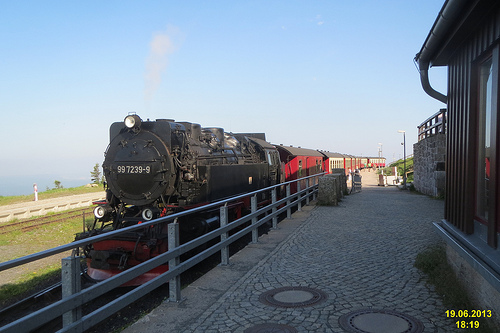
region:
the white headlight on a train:
[124, 115, 135, 127]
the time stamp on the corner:
[445, 309, 492, 329]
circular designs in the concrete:
[246, 283, 428, 332]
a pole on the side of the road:
[31, 184, 39, 199]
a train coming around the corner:
[78, 112, 385, 290]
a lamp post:
[397, 128, 405, 180]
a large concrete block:
[318, 174, 340, 207]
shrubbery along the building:
[413, 243, 498, 331]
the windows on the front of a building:
[468, 60, 498, 236]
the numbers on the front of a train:
[115, 163, 150, 175]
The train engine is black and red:
[86, 109, 285, 279]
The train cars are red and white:
[276, 142, 386, 202]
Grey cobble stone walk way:
[213, 177, 456, 330]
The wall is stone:
[408, 120, 444, 199]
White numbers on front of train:
[114, 160, 157, 177]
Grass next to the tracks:
[3, 178, 112, 300]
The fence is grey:
[8, 160, 320, 327]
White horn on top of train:
[120, 109, 143, 130]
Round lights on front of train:
[91, 199, 156, 226]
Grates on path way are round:
[248, 274, 420, 331]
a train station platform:
[124, 185, 468, 330]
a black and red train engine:
[77, 111, 283, 291]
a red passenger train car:
[275, 141, 325, 201]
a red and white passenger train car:
[321, 148, 344, 175]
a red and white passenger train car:
[344, 150, 352, 171]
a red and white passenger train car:
[360, 153, 367, 167]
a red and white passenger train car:
[369, 153, 386, 168]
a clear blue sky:
[4, 0, 451, 197]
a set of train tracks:
[0, 270, 174, 330]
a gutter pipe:
[418, 61, 445, 105]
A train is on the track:
[87, 85, 346, 263]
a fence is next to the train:
[87, 230, 349, 310]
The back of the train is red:
[267, 138, 365, 207]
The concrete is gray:
[276, 225, 402, 320]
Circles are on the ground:
[258, 271, 350, 330]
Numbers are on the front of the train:
[100, 151, 167, 186]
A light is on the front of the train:
[109, 113, 159, 135]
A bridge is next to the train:
[401, 111, 473, 153]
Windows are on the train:
[286, 154, 379, 193]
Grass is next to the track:
[20, 235, 63, 247]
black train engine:
[106, 104, 277, 181]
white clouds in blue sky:
[13, 18, 43, 50]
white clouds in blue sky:
[20, 90, 50, 122]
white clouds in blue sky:
[39, 40, 70, 94]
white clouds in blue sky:
[7, 91, 42, 135]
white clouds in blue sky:
[97, 33, 178, 80]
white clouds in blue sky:
[220, 47, 280, 115]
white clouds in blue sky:
[256, 31, 286, 75]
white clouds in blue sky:
[301, 60, 342, 102]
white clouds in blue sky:
[323, 60, 355, 127]